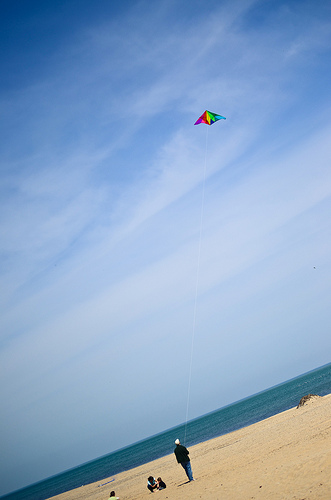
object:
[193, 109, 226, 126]
colorful kite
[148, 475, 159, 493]
woman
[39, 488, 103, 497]
sand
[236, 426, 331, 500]
ground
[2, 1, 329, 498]
blue sky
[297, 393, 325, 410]
hill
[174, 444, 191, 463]
jacket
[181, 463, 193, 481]
blue jeans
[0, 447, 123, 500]
water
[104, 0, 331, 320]
air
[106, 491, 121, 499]
person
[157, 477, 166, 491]
child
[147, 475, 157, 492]
child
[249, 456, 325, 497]
sand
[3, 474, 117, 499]
beach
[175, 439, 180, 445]
hat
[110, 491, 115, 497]
kite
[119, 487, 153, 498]
ground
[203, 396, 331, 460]
shore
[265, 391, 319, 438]
sand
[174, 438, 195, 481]
man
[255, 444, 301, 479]
beach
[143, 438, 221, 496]
beach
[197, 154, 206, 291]
string